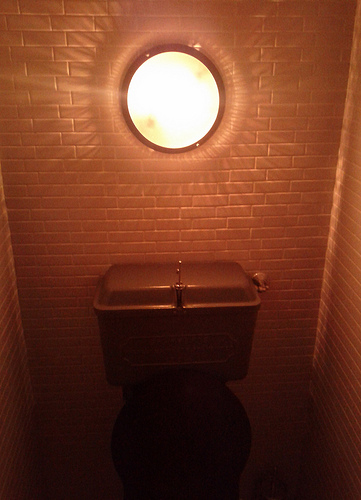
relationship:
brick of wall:
[218, 158, 254, 169] [234, 15, 342, 259]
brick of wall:
[232, 140, 268, 154] [234, 15, 342, 259]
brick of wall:
[255, 129, 294, 144] [234, 15, 342, 259]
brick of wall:
[269, 114, 306, 128] [234, 15, 342, 259]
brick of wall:
[270, 90, 309, 102] [234, 15, 342, 259]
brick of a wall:
[266, 192, 299, 206] [0, 17, 356, 306]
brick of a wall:
[227, 168, 265, 181] [0, 17, 356, 306]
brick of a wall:
[180, 206, 214, 220] [0, 17, 356, 306]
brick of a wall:
[67, 231, 105, 244] [0, 17, 356, 306]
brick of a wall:
[52, 304, 90, 318] [0, 17, 356, 306]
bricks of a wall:
[235, 222, 330, 259] [0, 17, 356, 306]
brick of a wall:
[280, 269, 325, 281] [267, 191, 301, 204]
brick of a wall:
[306, 258, 326, 268] [267, 191, 301, 204]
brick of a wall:
[295, 233, 329, 249] [267, 191, 301, 204]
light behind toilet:
[119, 43, 219, 152] [88, 255, 270, 498]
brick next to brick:
[306, 258, 326, 268] [264, 278, 293, 288]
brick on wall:
[21, 31, 66, 46] [0, 17, 356, 306]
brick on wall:
[25, 61, 68, 74] [0, 17, 356, 306]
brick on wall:
[13, 77, 56, 92] [0, 17, 356, 306]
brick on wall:
[16, 106, 59, 119] [0, 17, 356, 306]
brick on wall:
[19, 132, 60, 146] [0, 17, 356, 306]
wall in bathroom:
[0, 17, 356, 306] [1, 1, 360, 497]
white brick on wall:
[151, 196, 193, 206] [0, 17, 356, 306]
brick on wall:
[29, 89, 72, 102] [0, 17, 356, 306]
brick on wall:
[74, 144, 112, 161] [0, 17, 356, 306]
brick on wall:
[268, 143, 305, 155] [0, 17, 356, 306]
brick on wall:
[274, 62, 312, 72] [0, 17, 356, 306]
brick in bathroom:
[25, 61, 68, 74] [1, 1, 360, 497]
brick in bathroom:
[29, 89, 72, 102] [1, 1, 360, 497]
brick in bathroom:
[74, 144, 112, 161] [1, 1, 360, 497]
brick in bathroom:
[268, 143, 305, 155] [1, 1, 360, 497]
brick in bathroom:
[274, 62, 312, 72] [1, 1, 360, 497]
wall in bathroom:
[239, 185, 356, 222] [1, 1, 360, 497]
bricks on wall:
[229, 216, 297, 239] [0, 17, 356, 306]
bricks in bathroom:
[229, 216, 297, 239] [1, 1, 360, 497]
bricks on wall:
[267, 262, 317, 313] [0, 17, 356, 306]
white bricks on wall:
[4, 1, 356, 458] [0, 17, 356, 306]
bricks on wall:
[0, 0, 360, 497] [0, 17, 356, 306]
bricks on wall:
[249, 360, 304, 382] [0, 17, 356, 306]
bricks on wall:
[27, 86, 74, 108] [15, 22, 90, 163]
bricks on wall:
[270, 116, 322, 218] [0, 17, 356, 306]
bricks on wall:
[19, 24, 76, 90] [0, 17, 356, 306]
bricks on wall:
[245, 31, 315, 63] [15, 8, 322, 253]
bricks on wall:
[221, 185, 276, 213] [14, 7, 324, 415]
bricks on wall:
[269, 113, 326, 150] [14, 7, 324, 415]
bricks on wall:
[132, 201, 196, 236] [14, 7, 324, 415]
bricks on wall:
[22, 103, 72, 141] [14, 7, 324, 415]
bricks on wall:
[267, 59, 314, 79] [0, 17, 356, 306]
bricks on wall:
[259, 43, 302, 65] [0, 17, 356, 306]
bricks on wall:
[273, 28, 319, 45] [0, 17, 356, 306]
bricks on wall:
[233, 30, 276, 48] [0, 17, 356, 306]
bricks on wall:
[259, 13, 305, 35] [0, 17, 356, 306]